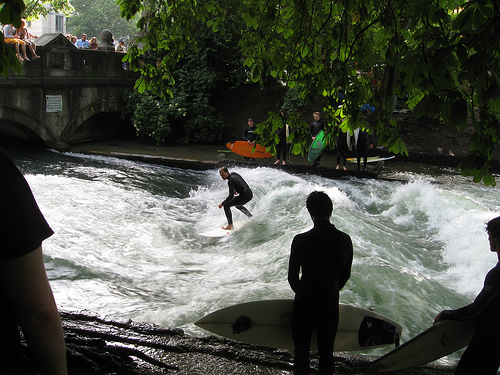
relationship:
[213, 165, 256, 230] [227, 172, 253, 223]
man in wetsuit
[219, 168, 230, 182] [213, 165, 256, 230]
head of man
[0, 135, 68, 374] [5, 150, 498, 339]
bystander near stream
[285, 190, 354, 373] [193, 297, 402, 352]
man holding surfboard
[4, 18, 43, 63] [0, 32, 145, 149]
onlookers are on bridge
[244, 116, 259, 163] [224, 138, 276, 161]
man holding surfboard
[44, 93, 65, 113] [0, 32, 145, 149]
sign on bridge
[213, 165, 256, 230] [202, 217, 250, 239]
man on surfboard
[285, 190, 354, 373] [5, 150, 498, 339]
man standing near stream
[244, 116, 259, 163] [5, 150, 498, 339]
man standing near stream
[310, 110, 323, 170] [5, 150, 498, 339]
man standing near stream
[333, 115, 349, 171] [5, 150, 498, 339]
man standing near stream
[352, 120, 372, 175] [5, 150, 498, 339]
man standing near stream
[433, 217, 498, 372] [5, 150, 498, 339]
man standing nears stream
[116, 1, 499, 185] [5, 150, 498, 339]
trees are hanging over stream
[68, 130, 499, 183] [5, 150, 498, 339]
path beside stream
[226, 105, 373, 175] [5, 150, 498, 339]
surfers on shore of stream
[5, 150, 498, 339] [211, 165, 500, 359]
stream has waves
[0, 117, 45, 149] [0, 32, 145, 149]
arch in bridge